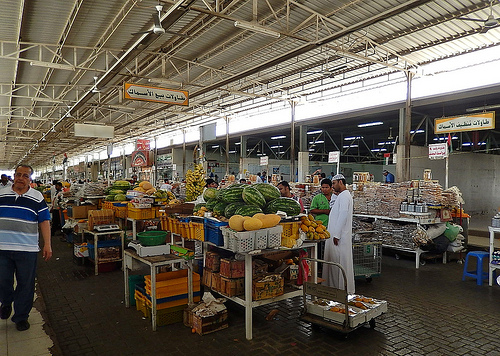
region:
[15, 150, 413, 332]
people in the market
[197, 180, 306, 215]
the water mellons are stacked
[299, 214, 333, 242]
mangoes beside the watermelons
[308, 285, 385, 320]
produce on the cart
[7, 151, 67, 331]
the man is walking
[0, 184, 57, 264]
the shirt is striped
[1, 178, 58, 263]
man wearing the striped shirt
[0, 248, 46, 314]
the man wearing the dark pants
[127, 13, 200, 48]
the fan on the ceiling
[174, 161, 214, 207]
a stack of bananas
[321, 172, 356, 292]
man with white cap wearing white robes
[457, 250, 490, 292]
bright blue plastic stool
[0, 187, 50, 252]
blue white and grey short sleeved shirt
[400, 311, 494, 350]
red brick floor with rectangular bricks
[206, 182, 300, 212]
bright green stripped water melon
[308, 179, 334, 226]
woman in bright green shirt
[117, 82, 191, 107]
orange and white sign with black writing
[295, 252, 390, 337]
brown metal cart with white packages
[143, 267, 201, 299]
stack of orange plastic containers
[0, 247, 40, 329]
dark blue denim pants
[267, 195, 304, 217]
A watermelon on a table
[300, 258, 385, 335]
A dolley carrying items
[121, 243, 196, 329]
A small table with a bowl on it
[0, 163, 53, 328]
A man wearing a blue and white shirt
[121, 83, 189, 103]
A sign written in arabic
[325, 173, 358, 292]
A man wearing a robe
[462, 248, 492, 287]
A blue plastic stool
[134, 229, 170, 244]
A green bowl on a table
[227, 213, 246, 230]
A canteloupe on a table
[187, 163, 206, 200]
A rack of bananas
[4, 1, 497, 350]
this is a large market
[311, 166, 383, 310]
he is wearing a white cap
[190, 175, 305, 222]
a pile of large watermelon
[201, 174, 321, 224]
the watermelon are green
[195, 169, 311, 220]
the watermelon have stripes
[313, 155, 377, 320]
he is wearing a long white robe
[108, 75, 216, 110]
the sign is white and yellow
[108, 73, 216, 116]
the sign is in Arabic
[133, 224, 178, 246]
a plastic green basket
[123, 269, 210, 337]
a stack of yellow plastic crates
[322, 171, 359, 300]
Man wearing a white gown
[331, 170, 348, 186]
Cap on man's hand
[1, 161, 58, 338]
Man wearing a striped shirt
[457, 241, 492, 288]
Blu stool on floor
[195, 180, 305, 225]
Stack of watermelons on table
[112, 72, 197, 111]
Sign hanging from ceiling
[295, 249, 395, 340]
Cart next to man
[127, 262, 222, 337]
Containers stacked under table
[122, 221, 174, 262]
Scale on the table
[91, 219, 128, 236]
Scale on a table